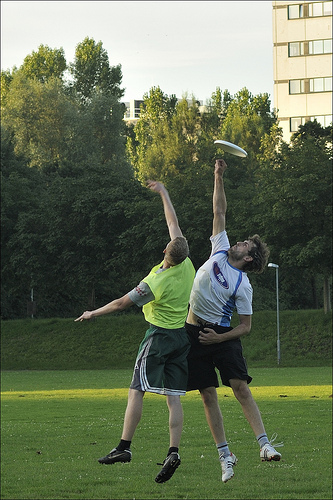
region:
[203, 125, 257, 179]
A white frisbee is flying through the air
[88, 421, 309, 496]
Two young men are jumping off the ground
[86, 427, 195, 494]
a pair of black cleats with black socks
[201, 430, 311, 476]
a pair of white cleats with gray socks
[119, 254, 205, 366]
a man wearing a neon yellow jersey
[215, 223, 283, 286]
a man with facial hair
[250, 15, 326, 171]
a sunlit building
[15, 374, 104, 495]
a field with white flowers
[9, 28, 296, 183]
sunlit trees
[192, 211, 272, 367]
a man wearing a white shirt and black shorts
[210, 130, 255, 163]
A white frisbee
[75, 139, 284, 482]
Two men playing outdoors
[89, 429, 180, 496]
A pair of black cleats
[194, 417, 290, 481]
A pair of white adidas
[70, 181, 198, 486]
A man in a neon yellow top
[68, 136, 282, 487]
Two men reaching for a frisbee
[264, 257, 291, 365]
A tall lamp post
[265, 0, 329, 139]
A white building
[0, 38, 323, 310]
A wall of trees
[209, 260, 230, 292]
A company logo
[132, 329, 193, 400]
The person is wearing shorts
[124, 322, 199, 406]
The person is wearing green shorts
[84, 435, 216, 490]
The person is wearing shoes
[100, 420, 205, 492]
The person is wearing black and white shoes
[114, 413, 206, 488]
The person is wearing socks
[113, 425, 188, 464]
The person is wearing black socks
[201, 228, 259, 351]
The man is wearing a shirt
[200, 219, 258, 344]
The man is wearing a blue and white shirt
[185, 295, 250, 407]
The man is wearing shorts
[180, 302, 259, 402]
The man is wearing black shorts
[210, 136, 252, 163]
white frisbee in the air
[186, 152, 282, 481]
man jumping for frisbee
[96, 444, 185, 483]
pair of black sneakers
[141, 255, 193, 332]
neon green shirt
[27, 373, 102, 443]
green grass of field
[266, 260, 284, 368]
tall metal lamp post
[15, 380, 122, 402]
sun shining through trees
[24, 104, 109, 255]
green leaves on trees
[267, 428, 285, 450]
flopping white shoe lace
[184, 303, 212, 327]
belly peeking through raised shirt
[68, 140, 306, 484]
Men in a field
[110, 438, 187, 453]
A black pair of socks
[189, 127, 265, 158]
A frisbee in the air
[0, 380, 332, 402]
Bright light on the ground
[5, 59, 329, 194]
Green leaves on branches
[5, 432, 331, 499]
Green grass in a field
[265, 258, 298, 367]
A lamp on a pole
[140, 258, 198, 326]
A bright colored shirt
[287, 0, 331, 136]
Windows on a building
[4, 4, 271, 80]
A clear sky